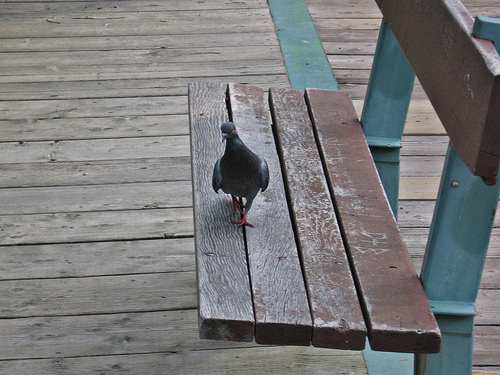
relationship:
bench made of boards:
[178, 3, 496, 375] [451, 48, 490, 174]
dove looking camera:
[209, 116, 272, 233] [2, 2, 500, 375]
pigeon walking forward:
[209, 116, 272, 233] [193, 106, 292, 324]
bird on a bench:
[209, 116, 272, 233] [178, 3, 496, 375]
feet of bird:
[229, 195, 256, 232] [209, 116, 272, 233]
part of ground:
[324, 8, 370, 56] [316, 2, 374, 46]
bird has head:
[209, 116, 272, 233] [215, 115, 246, 148]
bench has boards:
[178, 3, 496, 375] [451, 48, 490, 174]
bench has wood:
[178, 3, 496, 375] [183, 73, 442, 365]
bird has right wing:
[209, 116, 272, 233] [258, 155, 272, 195]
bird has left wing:
[209, 116, 272, 233] [211, 157, 225, 195]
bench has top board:
[178, 3, 496, 375] [183, 73, 442, 365]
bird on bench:
[209, 116, 272, 233] [178, 3, 496, 375]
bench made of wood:
[178, 3, 496, 375] [183, 73, 442, 365]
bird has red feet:
[209, 116, 272, 233] [229, 195, 256, 232]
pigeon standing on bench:
[209, 116, 272, 233] [178, 3, 496, 375]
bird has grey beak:
[209, 116, 272, 233] [218, 131, 230, 144]